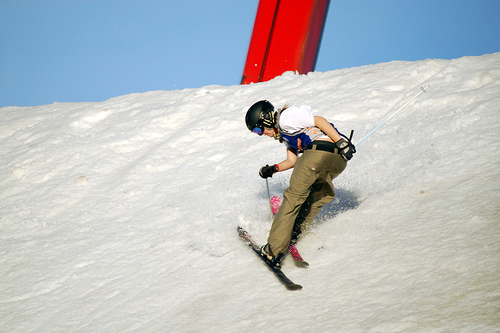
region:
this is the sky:
[7, 10, 88, 65]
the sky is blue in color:
[15, 16, 111, 74]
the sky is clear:
[3, 6, 202, 64]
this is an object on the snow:
[251, 1, 315, 68]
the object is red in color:
[262, 7, 309, 57]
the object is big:
[256, 1, 313, 66]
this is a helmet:
[248, 107, 263, 117]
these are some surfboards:
[239, 197, 302, 289]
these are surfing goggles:
[251, 125, 263, 136]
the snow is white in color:
[43, 141, 168, 289]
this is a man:
[239, 95, 355, 252]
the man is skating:
[216, 100, 366, 270]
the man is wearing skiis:
[235, 238, 317, 291]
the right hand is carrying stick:
[262, 180, 279, 194]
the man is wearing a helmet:
[245, 100, 266, 127]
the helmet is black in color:
[247, 103, 270, 126]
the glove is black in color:
[259, 161, 281, 176]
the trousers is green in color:
[294, 159, 333, 216]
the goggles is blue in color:
[257, 125, 263, 134]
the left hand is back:
[316, 134, 364, 147]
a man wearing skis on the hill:
[234, 97, 355, 285]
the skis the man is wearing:
[234, 212, 309, 294]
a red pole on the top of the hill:
[236, 2, 327, 87]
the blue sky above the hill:
[4, 1, 498, 102]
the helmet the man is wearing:
[243, 94, 273, 138]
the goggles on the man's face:
[255, 125, 262, 138]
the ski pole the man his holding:
[258, 165, 272, 202]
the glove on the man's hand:
[330, 135, 357, 162]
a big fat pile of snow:
[20, 129, 212, 311]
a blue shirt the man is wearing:
[273, 129, 308, 154]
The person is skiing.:
[226, 113, 344, 270]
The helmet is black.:
[240, 100, 279, 132]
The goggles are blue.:
[241, 118, 279, 152]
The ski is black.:
[271, 266, 297, 299]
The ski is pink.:
[293, 245, 311, 267]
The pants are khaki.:
[287, 166, 326, 203]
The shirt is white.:
[291, 112, 330, 132]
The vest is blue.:
[271, 129, 305, 151]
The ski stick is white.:
[368, 116, 397, 145]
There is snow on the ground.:
[109, 281, 189, 321]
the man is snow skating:
[210, 91, 377, 251]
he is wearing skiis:
[222, 227, 307, 295]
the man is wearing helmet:
[245, 101, 270, 127]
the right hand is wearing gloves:
[256, 167, 273, 177]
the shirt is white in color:
[284, 113, 308, 125]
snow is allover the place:
[2, 91, 231, 331]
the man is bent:
[237, 98, 339, 191]